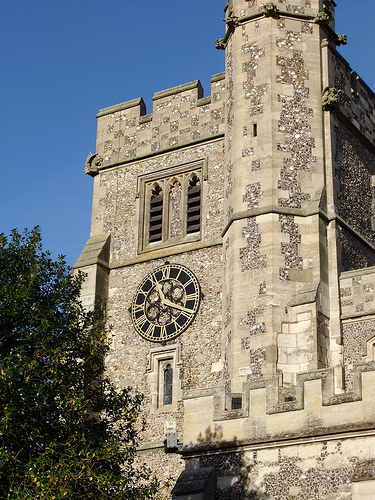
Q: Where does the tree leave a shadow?
A: On the building.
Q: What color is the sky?
A: Blue.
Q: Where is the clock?
A: Building.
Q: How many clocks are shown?
A: 1.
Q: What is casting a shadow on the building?
A: Tree.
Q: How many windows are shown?
A: 3.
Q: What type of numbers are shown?
A: Roman numerals.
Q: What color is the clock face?
A: Black.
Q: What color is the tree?
A: Green.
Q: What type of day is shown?
A: Clear.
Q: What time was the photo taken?
A: 11:19.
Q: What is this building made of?
A: Stone.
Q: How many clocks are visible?
A: 1.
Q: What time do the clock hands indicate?
A: 11:20.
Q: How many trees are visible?
A: 1.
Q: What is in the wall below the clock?
A: Window.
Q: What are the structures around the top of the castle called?
A: Parapets.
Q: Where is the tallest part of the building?
A: Right side.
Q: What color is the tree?
A: Green.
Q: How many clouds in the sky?
A: 0.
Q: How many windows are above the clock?
A: 2.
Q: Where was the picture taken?
A: At a church.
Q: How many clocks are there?
A: One.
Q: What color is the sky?
A: Blue.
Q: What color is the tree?
A: Green.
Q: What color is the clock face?
A: Black.